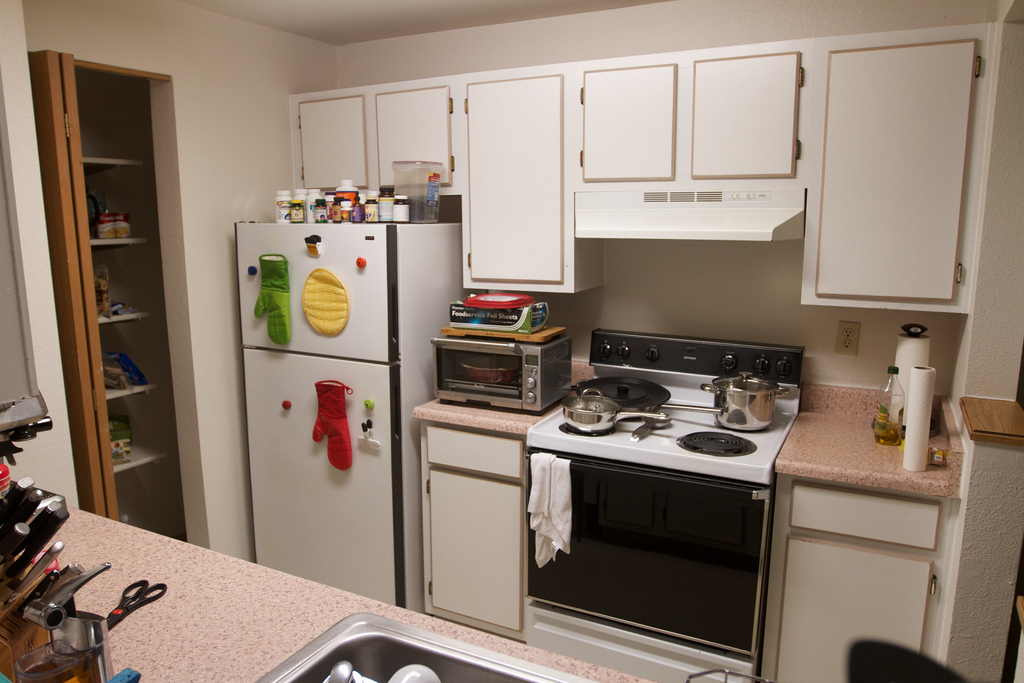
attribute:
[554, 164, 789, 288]
vent — white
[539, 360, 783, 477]
stovetop — white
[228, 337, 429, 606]
fridge — white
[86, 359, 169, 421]
shelf — white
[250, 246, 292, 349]
ovenmitt — green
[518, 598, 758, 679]
drawer — white